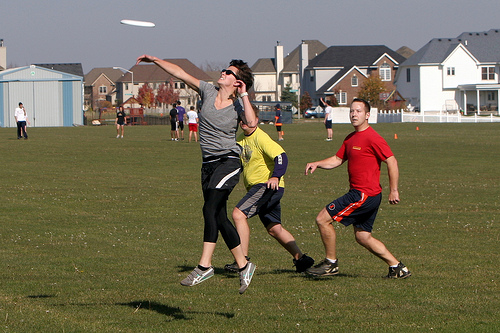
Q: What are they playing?
A: Frisbee.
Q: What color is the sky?
A: Gray.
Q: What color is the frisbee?
A: White.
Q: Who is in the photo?
A: Some people.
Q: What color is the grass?
A: Green.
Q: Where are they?
A: In a park.